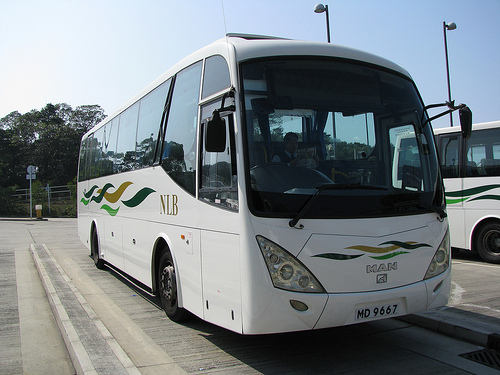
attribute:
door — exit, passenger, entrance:
[192, 113, 252, 339]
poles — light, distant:
[433, 13, 482, 123]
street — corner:
[12, 222, 61, 254]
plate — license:
[352, 295, 404, 321]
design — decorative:
[314, 232, 489, 264]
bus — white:
[31, 62, 416, 364]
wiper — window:
[282, 205, 341, 225]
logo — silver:
[364, 259, 403, 274]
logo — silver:
[154, 187, 179, 224]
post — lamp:
[436, 27, 468, 119]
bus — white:
[435, 118, 498, 260]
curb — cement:
[425, 311, 499, 349]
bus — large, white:
[390, 111, 497, 255]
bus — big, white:
[29, 42, 441, 291]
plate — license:
[332, 286, 424, 338]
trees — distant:
[2, 102, 108, 217]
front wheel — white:
[155, 248, 195, 323]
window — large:
[149, 63, 213, 203]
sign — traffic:
[23, 157, 40, 197]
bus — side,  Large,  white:
[67, 27, 479, 341]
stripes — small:
[24, 231, 152, 372]